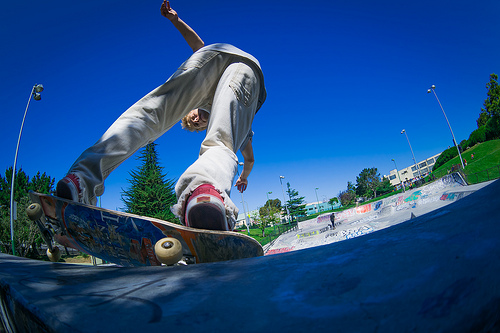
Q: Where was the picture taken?
A: It was taken at the skate park.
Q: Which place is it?
A: It is a skate park.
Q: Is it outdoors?
A: Yes, it is outdoors.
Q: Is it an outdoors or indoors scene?
A: It is outdoors.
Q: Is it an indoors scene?
A: No, it is outdoors.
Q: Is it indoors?
A: No, it is outdoors.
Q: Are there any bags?
A: No, there are no bags.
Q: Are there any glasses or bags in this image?
A: No, there are no bags or glasses.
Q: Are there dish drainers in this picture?
A: No, there are no dish drainers.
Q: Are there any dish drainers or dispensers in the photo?
A: No, there are no dish drainers or dispensers.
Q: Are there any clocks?
A: No, there are no clocks.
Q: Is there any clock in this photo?
A: No, there are no clocks.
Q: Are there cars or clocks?
A: No, there are no clocks or cars.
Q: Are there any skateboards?
A: Yes, there is a skateboard.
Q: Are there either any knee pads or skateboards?
A: Yes, there is a skateboard.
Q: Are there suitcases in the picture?
A: No, there are no suitcases.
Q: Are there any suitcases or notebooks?
A: No, there are no suitcases or notebooks.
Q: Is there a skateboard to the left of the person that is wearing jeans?
A: Yes, there is a skateboard to the left of the person.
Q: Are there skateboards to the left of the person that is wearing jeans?
A: Yes, there is a skateboard to the left of the person.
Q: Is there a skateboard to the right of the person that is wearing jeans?
A: No, the skateboard is to the left of the person.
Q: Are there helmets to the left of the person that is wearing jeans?
A: No, there is a skateboard to the left of the person.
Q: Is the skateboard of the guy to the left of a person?
A: Yes, the skateboard is to the left of a person.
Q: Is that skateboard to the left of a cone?
A: No, the skateboard is to the left of a person.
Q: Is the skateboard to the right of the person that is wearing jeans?
A: No, the skateboard is to the left of the person.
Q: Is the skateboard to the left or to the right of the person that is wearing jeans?
A: The skateboard is to the left of the person.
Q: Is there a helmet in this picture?
A: No, there are no helmets.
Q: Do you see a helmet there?
A: No, there are no helmets.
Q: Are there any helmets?
A: No, there are no helmets.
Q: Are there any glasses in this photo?
A: No, there are no glasses.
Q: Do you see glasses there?
A: No, there are no glasses.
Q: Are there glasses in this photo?
A: No, there are no glasses.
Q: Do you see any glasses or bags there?
A: No, there are no glasses or bags.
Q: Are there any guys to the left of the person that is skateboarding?
A: Yes, there is a guy to the left of the person.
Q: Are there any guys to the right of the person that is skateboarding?
A: No, the guy is to the left of the person.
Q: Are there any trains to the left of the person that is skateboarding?
A: No, there is a guy to the left of the person.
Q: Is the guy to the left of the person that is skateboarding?
A: Yes, the guy is to the left of the person.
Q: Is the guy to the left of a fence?
A: No, the guy is to the left of the person.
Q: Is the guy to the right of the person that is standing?
A: No, the guy is to the left of the person.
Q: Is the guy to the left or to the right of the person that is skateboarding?
A: The guy is to the left of the person.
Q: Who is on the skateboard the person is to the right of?
A: The guy is on the skateboard.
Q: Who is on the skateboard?
A: The guy is on the skateboard.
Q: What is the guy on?
A: The guy is on the skateboard.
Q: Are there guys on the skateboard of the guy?
A: Yes, there is a guy on the skateboard.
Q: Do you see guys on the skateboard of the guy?
A: Yes, there is a guy on the skateboard.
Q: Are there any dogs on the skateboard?
A: No, there is a guy on the skateboard.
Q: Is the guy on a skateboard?
A: Yes, the guy is on a skateboard.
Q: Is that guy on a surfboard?
A: No, the guy is on a skateboard.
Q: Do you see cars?
A: No, there are no cars.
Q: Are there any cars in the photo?
A: No, there are no cars.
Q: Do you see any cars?
A: No, there are no cars.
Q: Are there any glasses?
A: No, there are no glasses.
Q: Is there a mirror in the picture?
A: No, there are no mirrors.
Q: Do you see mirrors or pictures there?
A: No, there are no mirrors or pictures.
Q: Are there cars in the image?
A: No, there are no cars.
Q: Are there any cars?
A: No, there are no cars.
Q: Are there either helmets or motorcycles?
A: No, there are no helmets or motorcycles.